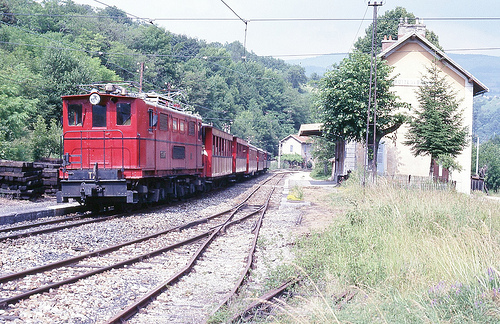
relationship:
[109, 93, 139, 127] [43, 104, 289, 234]
window on train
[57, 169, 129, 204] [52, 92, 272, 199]
ram on train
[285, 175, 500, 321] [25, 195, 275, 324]
grass by tracks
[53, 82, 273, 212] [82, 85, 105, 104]
train has light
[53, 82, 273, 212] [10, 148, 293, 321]
train on railroad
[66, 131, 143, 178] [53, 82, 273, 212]
gate in front train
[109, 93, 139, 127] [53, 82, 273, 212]
window in front train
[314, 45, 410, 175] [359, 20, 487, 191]
trees in front building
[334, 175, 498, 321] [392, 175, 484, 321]
grass on side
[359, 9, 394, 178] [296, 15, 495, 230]
pole in front house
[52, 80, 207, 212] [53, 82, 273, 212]
car of train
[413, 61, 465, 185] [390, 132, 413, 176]
tree on side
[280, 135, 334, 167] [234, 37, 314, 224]
building in background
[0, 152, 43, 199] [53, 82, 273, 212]
pallet stacked by train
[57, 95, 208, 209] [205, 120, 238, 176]
line of cars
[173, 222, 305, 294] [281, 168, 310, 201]
tracks disappearing into grass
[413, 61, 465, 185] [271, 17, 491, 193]
tree beside depot